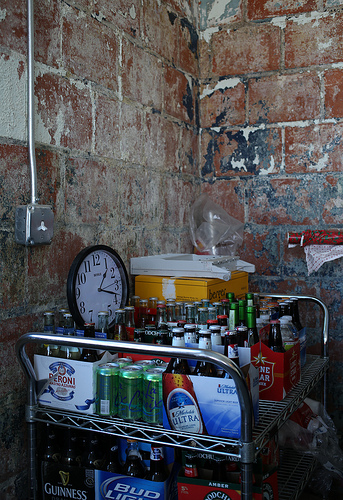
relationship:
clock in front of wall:
[70, 245, 128, 329] [0, 1, 343, 498]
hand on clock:
[94, 264, 114, 289] [68, 242, 129, 336]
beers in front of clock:
[43, 297, 310, 425] [63, 240, 132, 337]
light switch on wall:
[20, 203, 59, 248] [1, 4, 342, 316]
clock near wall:
[70, 245, 128, 329] [0, 2, 199, 327]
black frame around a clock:
[64, 243, 130, 327] [61, 243, 139, 330]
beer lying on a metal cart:
[32, 237, 342, 457] [16, 289, 327, 492]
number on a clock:
[89, 253, 102, 266] [60, 239, 136, 333]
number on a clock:
[75, 299, 86, 312] [60, 239, 136, 333]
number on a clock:
[73, 269, 86, 287] [60, 239, 136, 333]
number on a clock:
[100, 257, 109, 269] [60, 239, 136, 333]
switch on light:
[38, 218, 47, 234] [33, 209, 54, 241]